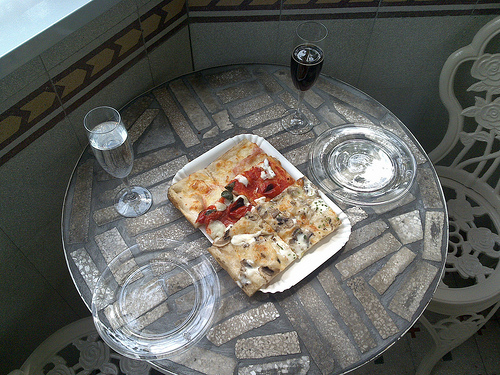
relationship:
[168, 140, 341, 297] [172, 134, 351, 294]
pizza on top of plate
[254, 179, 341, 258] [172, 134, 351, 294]
pizza on top of plate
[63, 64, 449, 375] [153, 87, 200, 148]
table has inlaid stone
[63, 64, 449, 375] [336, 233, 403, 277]
table has inlaid stone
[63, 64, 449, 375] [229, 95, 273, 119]
table has inlaid stone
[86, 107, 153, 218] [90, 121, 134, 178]
glass has water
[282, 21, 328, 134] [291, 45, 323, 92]
glass has soda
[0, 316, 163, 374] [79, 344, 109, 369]
chair has flower design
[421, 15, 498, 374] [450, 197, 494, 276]
chair has flower design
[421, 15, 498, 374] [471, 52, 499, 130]
chair has flower design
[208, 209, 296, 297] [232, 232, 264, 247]
pizza has mushroom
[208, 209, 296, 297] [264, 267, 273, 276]
pizza has mushroom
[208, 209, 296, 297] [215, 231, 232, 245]
pizza has mushroom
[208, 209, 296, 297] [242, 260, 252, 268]
pizza has mushroom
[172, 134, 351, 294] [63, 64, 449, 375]
plate on top of table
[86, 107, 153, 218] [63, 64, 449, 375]
glass on top of table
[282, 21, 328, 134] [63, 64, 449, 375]
glass on top of table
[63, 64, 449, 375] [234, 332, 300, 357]
table has inlaid stone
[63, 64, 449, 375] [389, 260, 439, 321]
table has inlaid stone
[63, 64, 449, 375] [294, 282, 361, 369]
table has inlaid stone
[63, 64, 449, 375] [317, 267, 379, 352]
table has inlaid stone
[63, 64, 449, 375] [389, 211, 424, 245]
table has inlaid stone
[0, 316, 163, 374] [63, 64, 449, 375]
chair next to table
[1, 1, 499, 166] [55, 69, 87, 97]
border has yellow arrow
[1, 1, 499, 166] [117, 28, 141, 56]
border has yellow arrow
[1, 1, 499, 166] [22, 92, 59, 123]
border has yellow arrow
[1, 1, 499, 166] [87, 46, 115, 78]
border has yellow arrow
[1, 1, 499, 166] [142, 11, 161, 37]
border has yellow arrow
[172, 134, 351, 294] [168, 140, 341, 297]
plate has pizza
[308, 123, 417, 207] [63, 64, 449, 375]
plate on top of table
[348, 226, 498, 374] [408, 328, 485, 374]
ground has brick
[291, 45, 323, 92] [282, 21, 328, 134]
soda inside of glass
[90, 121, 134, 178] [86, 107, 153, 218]
water inside of glass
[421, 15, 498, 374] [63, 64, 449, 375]
chair next to table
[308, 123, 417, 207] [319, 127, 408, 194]
plate has reflection